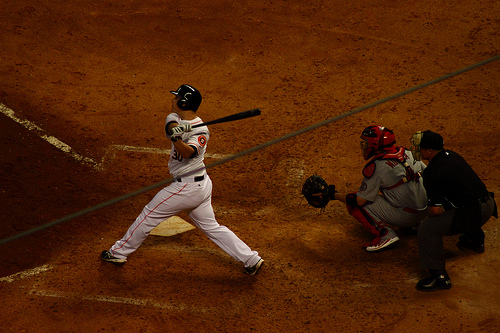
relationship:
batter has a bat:
[104, 83, 264, 272] [166, 105, 264, 139]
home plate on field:
[139, 215, 195, 236] [9, 6, 497, 326]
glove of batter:
[172, 125, 198, 136] [104, 83, 264, 272]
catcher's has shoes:
[305, 125, 417, 251] [368, 229, 406, 255]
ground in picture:
[9, 6, 497, 326] [3, 4, 500, 329]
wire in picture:
[6, 55, 496, 234] [3, 4, 500, 329]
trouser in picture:
[116, 178, 258, 267] [3, 4, 500, 329]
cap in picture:
[165, 86, 203, 112] [3, 4, 500, 329]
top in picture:
[162, 116, 221, 172] [3, 4, 500, 329]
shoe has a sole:
[368, 229, 406, 255] [368, 237, 402, 250]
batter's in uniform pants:
[104, 83, 264, 272] [116, 178, 258, 267]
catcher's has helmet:
[305, 125, 417, 251] [362, 122, 405, 160]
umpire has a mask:
[411, 129, 496, 312] [411, 132, 426, 154]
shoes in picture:
[368, 229, 406, 255] [3, 4, 500, 329]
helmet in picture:
[362, 122, 405, 160] [3, 4, 500, 329]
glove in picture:
[298, 178, 348, 205] [3, 4, 500, 329]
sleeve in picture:
[360, 164, 381, 204] [3, 4, 500, 329]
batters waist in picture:
[172, 153, 216, 179] [3, 4, 500, 329]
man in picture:
[104, 83, 264, 272] [3, 4, 500, 329]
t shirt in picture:
[162, 116, 221, 172] [3, 4, 500, 329]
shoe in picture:
[368, 229, 406, 255] [3, 4, 500, 329]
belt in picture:
[460, 191, 490, 211] [3, 4, 500, 329]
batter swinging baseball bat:
[104, 83, 264, 272] [166, 105, 264, 139]